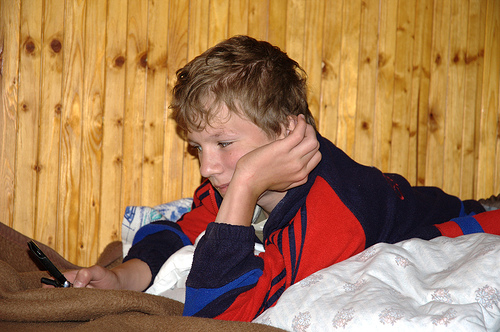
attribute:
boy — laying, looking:
[178, 63, 357, 229]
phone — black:
[18, 236, 70, 288]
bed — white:
[352, 236, 499, 315]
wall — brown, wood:
[50, 10, 146, 105]